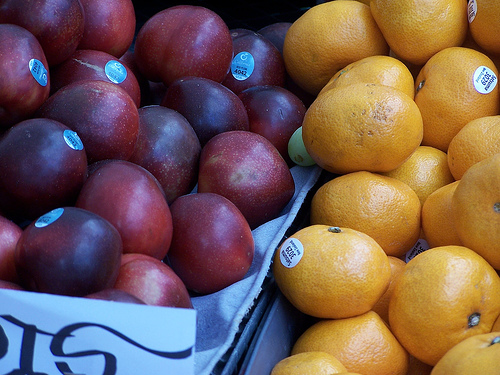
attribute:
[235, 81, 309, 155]
fruit — bright red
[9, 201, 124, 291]
plum — red